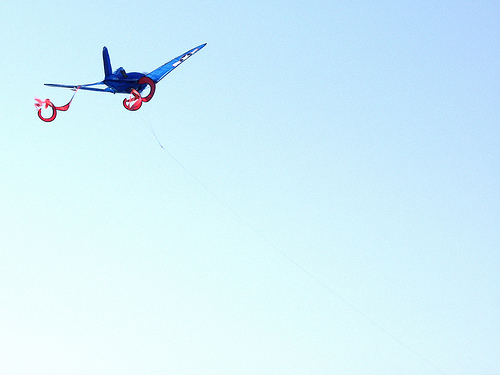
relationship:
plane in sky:
[37, 29, 217, 123] [276, 62, 326, 108]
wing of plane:
[152, 46, 207, 68] [37, 29, 217, 123]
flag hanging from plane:
[33, 93, 70, 124] [37, 29, 217, 123]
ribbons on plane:
[33, 93, 70, 124] [37, 29, 217, 123]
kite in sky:
[37, 29, 217, 123] [276, 62, 326, 108]